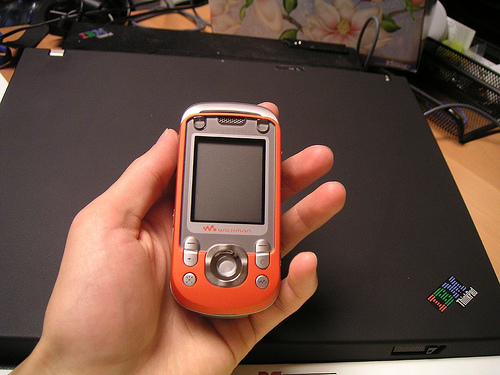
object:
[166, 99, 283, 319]
phone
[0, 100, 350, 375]
hand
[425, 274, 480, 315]
logo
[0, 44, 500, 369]
laptop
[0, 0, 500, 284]
table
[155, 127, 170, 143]
nails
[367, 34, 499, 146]
holder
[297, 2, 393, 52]
flower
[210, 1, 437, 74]
box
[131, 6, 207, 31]
wires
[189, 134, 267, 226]
screen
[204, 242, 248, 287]
button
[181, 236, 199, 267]
button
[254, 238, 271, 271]
button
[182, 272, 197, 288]
button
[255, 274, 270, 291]
button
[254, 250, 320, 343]
pinky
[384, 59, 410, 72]
kleenex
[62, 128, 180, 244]
thumb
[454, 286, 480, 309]
letters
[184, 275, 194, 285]
x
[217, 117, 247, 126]
speaker